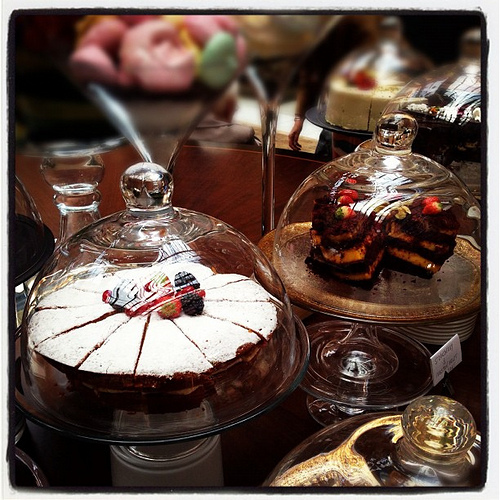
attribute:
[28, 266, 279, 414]
cake — white powdered, white, delicious looking, chocolate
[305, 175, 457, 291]
cake — missing slice, with filling, brown, partially eaten, chocolate, carmel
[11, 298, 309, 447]
platter — glass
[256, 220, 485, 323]
platter — glass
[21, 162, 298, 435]
lid — glass, made of glass, dome, clear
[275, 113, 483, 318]
lid — glass, made of glass, dome, see through, clear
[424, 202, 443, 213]
strawberry — red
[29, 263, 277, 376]
frosting — white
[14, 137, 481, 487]
table — wood, brown, wooden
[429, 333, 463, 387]
sign — white, handwritten, black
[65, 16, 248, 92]
dessert — pink, green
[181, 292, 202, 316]
berry — black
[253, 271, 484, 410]
cake stand — glass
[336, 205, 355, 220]
strawberry — red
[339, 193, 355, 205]
strawberry — red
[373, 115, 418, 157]
knob — glass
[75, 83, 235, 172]
cup — glass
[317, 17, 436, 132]
container — glass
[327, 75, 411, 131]
pastry — beige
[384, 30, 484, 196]
container — glass